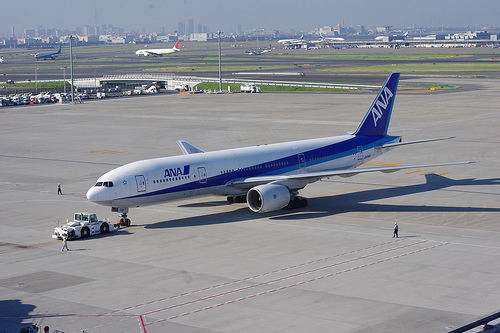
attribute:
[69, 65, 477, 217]
plane — jumbo jet, enroute, white, blue, large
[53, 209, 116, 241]
vehicle — white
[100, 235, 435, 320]
lines — red, striped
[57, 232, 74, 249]
man — standing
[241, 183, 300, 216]
engine — hanging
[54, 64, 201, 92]
bridge — small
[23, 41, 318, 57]
airplanes — rolling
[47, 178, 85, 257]
men — walking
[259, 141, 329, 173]
stripes — blue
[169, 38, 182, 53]
tail — red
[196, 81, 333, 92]
grass — green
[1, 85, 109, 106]
vehicles — parked